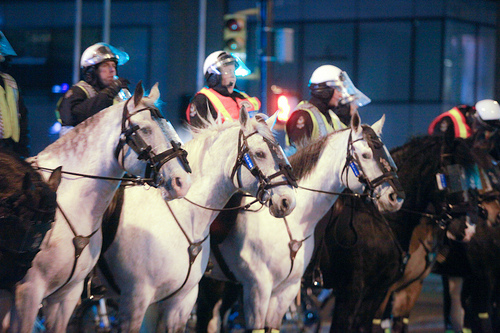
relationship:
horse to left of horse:
[78, 103, 296, 330] [15, 107, 202, 249]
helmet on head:
[312, 63, 338, 93] [309, 64, 351, 109]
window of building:
[303, 22, 351, 67] [3, 0, 498, 142]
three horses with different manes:
[7, 97, 412, 331] [22, 102, 389, 189]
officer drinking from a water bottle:
[55, 42, 135, 125] [111, 72, 132, 98]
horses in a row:
[17, 86, 192, 330] [4, 77, 406, 331]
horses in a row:
[132, 92, 295, 330] [4, 77, 406, 331]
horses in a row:
[248, 115, 410, 331] [4, 77, 406, 331]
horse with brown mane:
[202, 112, 406, 333] [278, 125, 348, 185]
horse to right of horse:
[193, 120, 483, 330] [198, 107, 404, 331]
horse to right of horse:
[193, 120, 483, 330] [78, 103, 296, 330]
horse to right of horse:
[193, 120, 483, 330] [1, 80, 196, 332]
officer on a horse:
[282, 43, 380, 166] [188, 102, 435, 325]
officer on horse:
[50, 40, 134, 122] [20, 82, 193, 331]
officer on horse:
[181, 42, 261, 133] [194, 97, 297, 234]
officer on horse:
[282, 61, 354, 156] [297, 102, 412, 220]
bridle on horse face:
[238, 153, 263, 181] [217, 117, 302, 222]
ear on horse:
[361, 115, 388, 135] [151, 112, 411, 331]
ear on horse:
[348, 104, 363, 133] [198, 107, 404, 331]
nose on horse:
[277, 194, 290, 214] [78, 103, 296, 330]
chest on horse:
[229, 215, 307, 331] [211, 157, 333, 277]